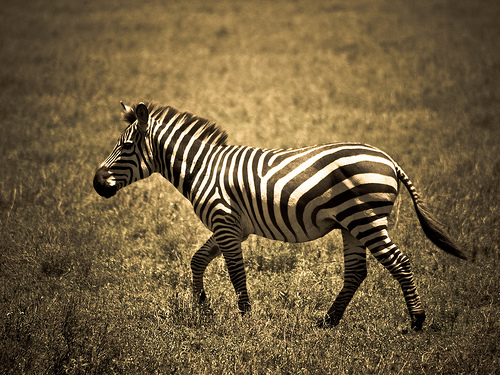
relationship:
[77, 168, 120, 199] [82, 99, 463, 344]
nose of zebra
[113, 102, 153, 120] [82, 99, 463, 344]
ear of zebra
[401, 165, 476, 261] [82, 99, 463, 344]
tail of zebra